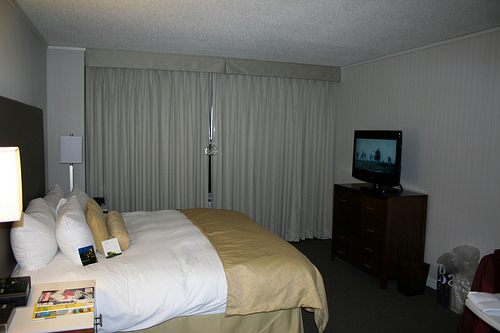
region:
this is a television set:
[353, 128, 410, 190]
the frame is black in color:
[396, 140, 398, 170]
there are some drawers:
[331, 187, 380, 273]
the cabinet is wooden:
[392, 210, 425, 243]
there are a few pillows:
[16, 202, 131, 268]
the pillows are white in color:
[32, 215, 77, 242]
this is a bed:
[133, 208, 310, 331]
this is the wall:
[376, 70, 471, 112]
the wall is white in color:
[416, 80, 478, 143]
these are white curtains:
[98, 72, 329, 216]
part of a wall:
[422, 97, 491, 179]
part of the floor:
[324, 269, 371, 320]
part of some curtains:
[250, 132, 317, 206]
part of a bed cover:
[230, 258, 297, 308]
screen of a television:
[351, 138, 394, 178]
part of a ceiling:
[251, 6, 332, 41]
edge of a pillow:
[68, 231, 100, 275]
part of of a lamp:
[0, 172, 26, 212]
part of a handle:
[477, 250, 493, 288]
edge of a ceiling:
[351, 53, 372, 68]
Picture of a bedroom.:
[18, 24, 463, 321]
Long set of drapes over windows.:
[75, 44, 335, 245]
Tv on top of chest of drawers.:
[343, 118, 410, 198]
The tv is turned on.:
[334, 112, 421, 203]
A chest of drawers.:
[324, 172, 432, 294]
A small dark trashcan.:
[383, 255, 439, 308]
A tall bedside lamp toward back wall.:
[46, 117, 91, 190]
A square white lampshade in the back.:
[51, 128, 93, 176]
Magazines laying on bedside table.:
[13, 267, 112, 328]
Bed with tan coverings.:
[34, 172, 356, 331]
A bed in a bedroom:
[20, 184, 339, 331]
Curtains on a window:
[204, 58, 342, 242]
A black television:
[345, 122, 412, 197]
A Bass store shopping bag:
[435, 237, 485, 314]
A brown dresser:
[326, 174, 431, 286]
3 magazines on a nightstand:
[34, 286, 95, 322]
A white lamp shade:
[57, 128, 86, 170]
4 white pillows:
[12, 177, 91, 266]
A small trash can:
[390, 257, 435, 301]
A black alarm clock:
[1, 272, 33, 307]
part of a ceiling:
[363, 1, 413, 43]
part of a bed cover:
[253, 251, 293, 296]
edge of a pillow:
[57, 211, 84, 246]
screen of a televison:
[366, 137, 393, 165]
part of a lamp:
[0, 183, 36, 236]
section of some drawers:
[336, 195, 373, 243]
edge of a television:
[394, 135, 404, 182]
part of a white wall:
[444, 142, 489, 222]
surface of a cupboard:
[53, 309, 82, 326]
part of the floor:
[335, 281, 388, 325]